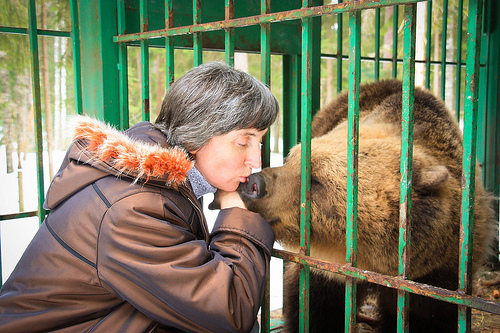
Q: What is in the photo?
A: Bear.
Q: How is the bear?
A: Social.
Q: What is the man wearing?
A: A coat.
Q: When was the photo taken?
A: Daytime.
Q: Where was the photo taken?
A: The zoo.